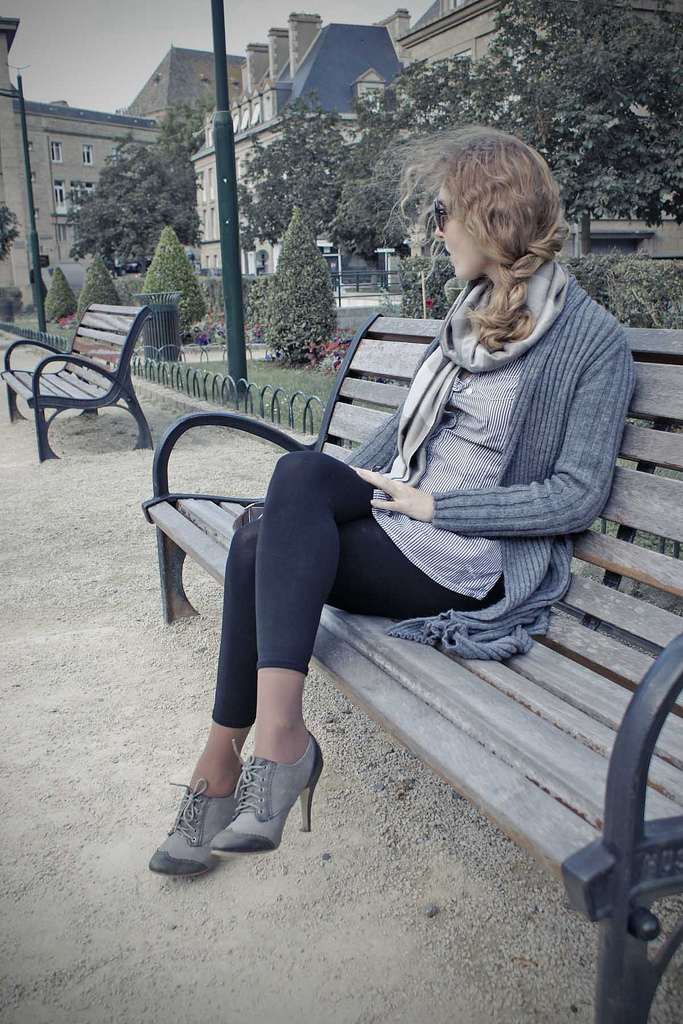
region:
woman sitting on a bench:
[146, 149, 634, 880]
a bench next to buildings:
[4, 295, 155, 451]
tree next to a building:
[268, 202, 337, 367]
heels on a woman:
[151, 729, 327, 882]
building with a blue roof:
[192, 19, 402, 264]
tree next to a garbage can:
[143, 221, 206, 342]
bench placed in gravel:
[7, 297, 158, 460]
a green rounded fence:
[132, 350, 322, 426]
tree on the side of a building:
[73, 148, 195, 270]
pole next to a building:
[12, 69, 60, 329]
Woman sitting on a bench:
[146, 126, 629, 876]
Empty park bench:
[0, 298, 152, 456]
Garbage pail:
[136, 289, 184, 363]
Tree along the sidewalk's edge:
[262, 204, 338, 363]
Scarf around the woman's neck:
[394, 256, 569, 493]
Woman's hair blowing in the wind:
[397, 124, 553, 242]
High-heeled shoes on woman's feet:
[147, 732, 323, 881]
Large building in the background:
[0, 0, 682, 330]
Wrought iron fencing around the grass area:
[6, 323, 325, 426]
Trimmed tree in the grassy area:
[137, 221, 205, 330]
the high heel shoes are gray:
[146, 732, 319, 873]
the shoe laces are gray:
[143, 731, 320, 872]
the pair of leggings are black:
[209, 449, 502, 729]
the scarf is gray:
[389, 259, 569, 487]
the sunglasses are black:
[432, 197, 453, 231]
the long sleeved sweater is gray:
[346, 267, 634, 659]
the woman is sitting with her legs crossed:
[149, 125, 636, 881]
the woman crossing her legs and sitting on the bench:
[140, 127, 680, 1022]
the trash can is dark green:
[129, 291, 184, 364]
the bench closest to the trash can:
[1, 288, 186, 461]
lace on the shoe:
[243, 768, 265, 781]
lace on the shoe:
[187, 775, 202, 795]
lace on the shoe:
[239, 764, 265, 774]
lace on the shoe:
[182, 820, 198, 830]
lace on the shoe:
[170, 779, 185, 789]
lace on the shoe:
[238, 764, 255, 779]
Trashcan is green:
[135, 289, 180, 362]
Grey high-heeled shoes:
[147, 736, 319, 877]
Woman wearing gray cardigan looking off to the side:
[155, 136, 631, 870]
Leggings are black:
[213, 447, 486, 725]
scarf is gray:
[386, 262, 563, 481]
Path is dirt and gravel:
[2, 325, 610, 1019]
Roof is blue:
[191, 21, 415, 153]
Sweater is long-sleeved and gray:
[340, 282, 633, 655]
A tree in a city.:
[268, 202, 343, 382]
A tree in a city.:
[144, 234, 202, 326]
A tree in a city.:
[71, 249, 125, 317]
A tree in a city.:
[41, 265, 80, 319]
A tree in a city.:
[78, 117, 191, 283]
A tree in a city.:
[242, 88, 333, 267]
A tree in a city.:
[325, 92, 394, 254]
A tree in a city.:
[158, 99, 202, 179]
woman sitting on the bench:
[160, 125, 607, 901]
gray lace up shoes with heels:
[141, 742, 318, 881]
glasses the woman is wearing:
[429, 195, 451, 226]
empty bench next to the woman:
[14, 284, 166, 457]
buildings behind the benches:
[12, 0, 593, 325]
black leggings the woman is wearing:
[190, 455, 471, 719]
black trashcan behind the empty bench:
[136, 283, 185, 358]